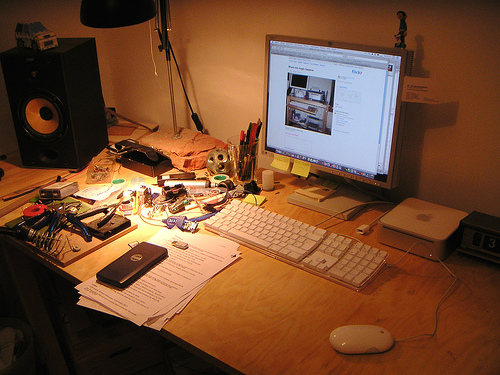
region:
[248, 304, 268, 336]
part of a o=line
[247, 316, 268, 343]
aprt of a wood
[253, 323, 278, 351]
aprt of a woor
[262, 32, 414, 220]
A desk top computer monitor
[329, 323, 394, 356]
A white Apple computer mouse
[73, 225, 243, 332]
A messy stack of papers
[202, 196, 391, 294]
A white and silver keyboard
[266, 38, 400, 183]
A back lit computer screen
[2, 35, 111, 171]
A black speaker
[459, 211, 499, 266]
A back digital clock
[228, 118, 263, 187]
A cup full of pens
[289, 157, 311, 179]
A yellow Post It note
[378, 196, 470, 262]
A desk top computer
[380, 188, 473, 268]
an Apple mini computer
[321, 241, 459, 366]
an oval white computer mouse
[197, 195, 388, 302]
a white computer keyboard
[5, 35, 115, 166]
a black speaker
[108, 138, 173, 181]
a greyish stapler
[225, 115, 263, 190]
a glass with pencils and pens in it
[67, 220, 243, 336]
a pile of papers with a black phone on it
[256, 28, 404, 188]
a computer monitor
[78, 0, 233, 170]
an adjustable desk lamp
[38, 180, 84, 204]
a box of staples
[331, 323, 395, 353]
White mouse on a wooden desk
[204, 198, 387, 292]
A keyboard with white keys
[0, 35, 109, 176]
A black speaker sitting on a desk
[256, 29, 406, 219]
A white computer monitor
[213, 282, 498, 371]
Light wood of a computer desk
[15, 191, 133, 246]
Tools on a desk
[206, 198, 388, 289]
White keys of a keyboard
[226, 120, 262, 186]
Tall glass full of pens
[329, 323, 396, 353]
A white mouse on the desk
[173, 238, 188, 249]
A USB flash drive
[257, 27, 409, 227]
Computer monitor sitting on desk.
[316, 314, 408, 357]
Computer mouse sitting on desk.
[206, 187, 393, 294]
Computer keyboard lying on desk.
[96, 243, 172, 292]
Black book lying on desk.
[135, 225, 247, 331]
White papers lying on desk.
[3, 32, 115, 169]
Huge speaker sitting in corner of desk.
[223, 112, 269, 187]
Glass filled with pens.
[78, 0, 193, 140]
Lamp mounted on desk.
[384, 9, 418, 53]
Toy figure mounted on top of computer monitor.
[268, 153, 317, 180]
Yellow post it notes on bottom on computer monitor.